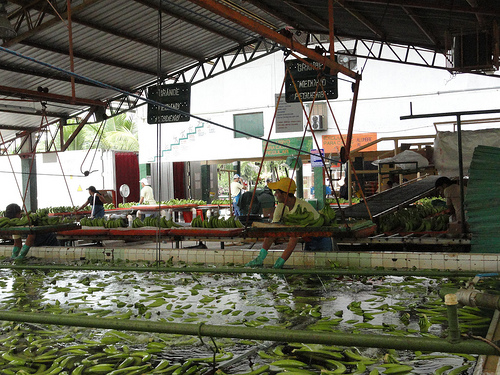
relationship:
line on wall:
[146, 118, 212, 163] [137, 46, 499, 160]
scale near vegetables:
[111, 175, 160, 212] [114, 200, 164, 210]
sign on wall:
[270, 90, 309, 134] [266, 91, 315, 137]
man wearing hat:
[249, 175, 335, 272] [265, 175, 295, 193]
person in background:
[73, 180, 100, 217] [53, 175, 141, 221]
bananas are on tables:
[0, 200, 238, 227] [0, 218, 382, 245]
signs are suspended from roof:
[142, 47, 344, 128] [144, 13, 384, 62]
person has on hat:
[261, 184, 333, 253] [264, 177, 295, 190]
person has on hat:
[261, 184, 333, 253] [266, 173, 296, 194]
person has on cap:
[261, 184, 333, 253] [264, 178, 295, 192]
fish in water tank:
[108, 333, 178, 373] [4, 247, 484, 359]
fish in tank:
[319, 284, 388, 333] [43, 217, 497, 372]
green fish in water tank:
[271, 359, 306, 366] [1, 255, 499, 373]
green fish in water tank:
[385, 365, 412, 374] [1, 255, 499, 373]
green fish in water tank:
[208, 350, 234, 363] [1, 255, 499, 373]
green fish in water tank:
[309, 307, 320, 314] [1, 255, 499, 373]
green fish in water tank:
[86, 361, 113, 371] [1, 255, 499, 373]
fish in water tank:
[318, 351, 345, 370] [4, 247, 484, 359]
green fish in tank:
[9, 273, 437, 355] [280, 235, 377, 318]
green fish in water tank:
[9, 273, 437, 369] [20, 250, 450, 372]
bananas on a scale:
[263, 197, 377, 250] [150, 5, 400, 261]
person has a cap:
[261, 184, 333, 253] [266, 174, 296, 194]